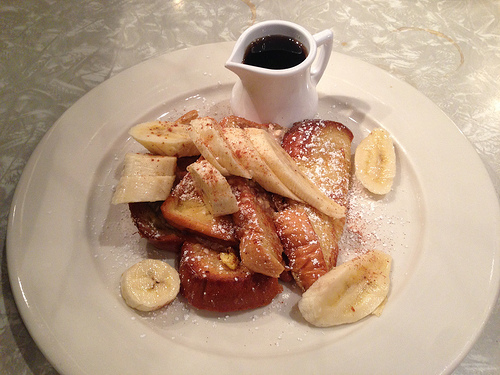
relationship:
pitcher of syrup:
[225, 18, 335, 118] [260, 43, 290, 66]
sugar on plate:
[315, 155, 400, 256] [6, 32, 499, 373]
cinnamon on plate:
[340, 172, 410, 267] [6, 32, 499, 373]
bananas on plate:
[111, 110, 397, 328] [6, 42, 499, 373]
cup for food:
[224, 19, 333, 129] [122, 111, 412, 321]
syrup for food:
[241, 32, 308, 68] [122, 111, 412, 321]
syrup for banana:
[241, 32, 308, 68] [353, 126, 398, 197]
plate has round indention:
[6, 32, 499, 373] [85, 81, 432, 363]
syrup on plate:
[214, 17, 342, 136] [6, 32, 499, 373]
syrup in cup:
[241, 32, 308, 68] [219, 11, 339, 120]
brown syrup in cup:
[180, 232, 277, 298] [219, 11, 339, 120]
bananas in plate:
[111, 110, 397, 328] [6, 32, 499, 373]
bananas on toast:
[105, 72, 412, 329] [206, 100, 351, 282]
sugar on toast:
[297, 127, 382, 247] [264, 115, 361, 294]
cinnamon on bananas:
[208, 118, 251, 167] [111, 112, 409, 333]